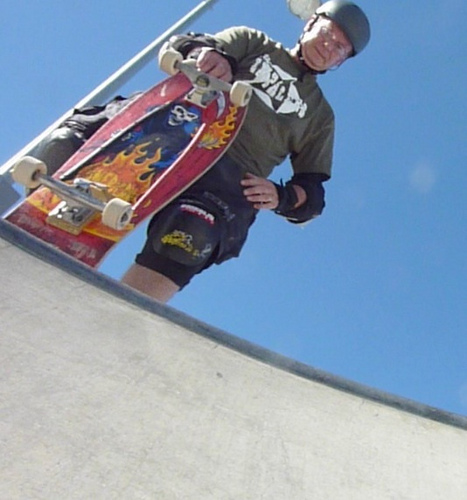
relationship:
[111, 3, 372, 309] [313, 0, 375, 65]
man wearing a helmet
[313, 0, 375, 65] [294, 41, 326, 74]
helmet has chin strap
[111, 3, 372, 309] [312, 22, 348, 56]
man wearing helmet has eyeglasses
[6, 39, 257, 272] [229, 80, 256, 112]
skateboard has wheel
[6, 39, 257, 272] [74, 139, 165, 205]
skateboard has flame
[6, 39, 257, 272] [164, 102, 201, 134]
skateboard has face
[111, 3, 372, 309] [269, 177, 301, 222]
man wearing wrist guards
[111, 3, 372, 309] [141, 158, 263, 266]
man wearing shorts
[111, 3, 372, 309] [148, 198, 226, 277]
man wearing knee pad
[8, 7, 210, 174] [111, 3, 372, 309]
pole behind man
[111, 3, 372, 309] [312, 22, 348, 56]
man wearing eyeglasses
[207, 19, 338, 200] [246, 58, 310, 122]
shirt has white picture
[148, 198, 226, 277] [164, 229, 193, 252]
knee pad has picture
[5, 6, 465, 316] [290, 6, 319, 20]
sky has no clouds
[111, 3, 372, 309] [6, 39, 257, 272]
man holding skateboard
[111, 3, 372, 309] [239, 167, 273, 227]
man has hand on hip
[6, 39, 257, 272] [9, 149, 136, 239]
skateboard has back wheels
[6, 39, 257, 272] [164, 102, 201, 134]
skateboard has a picture of face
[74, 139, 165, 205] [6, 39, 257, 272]
flame on skateboard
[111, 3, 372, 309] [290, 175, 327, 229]
man wearing an elbow pad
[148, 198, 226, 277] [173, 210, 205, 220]
knee pad has purple letters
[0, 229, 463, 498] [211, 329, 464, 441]
ramp has a lip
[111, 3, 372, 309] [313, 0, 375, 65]
man wearing a green helmet